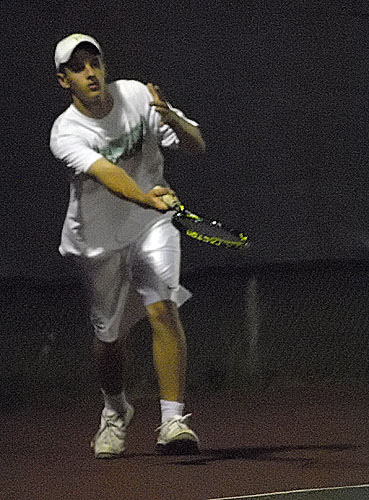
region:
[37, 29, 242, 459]
tennis player wearing all white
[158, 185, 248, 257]
black and yellow tennis racket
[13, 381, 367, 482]
brown part of tennis court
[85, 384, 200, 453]
white shoes and socks of tennis player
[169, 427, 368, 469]
shadow of player on court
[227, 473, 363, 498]
white line on tennis court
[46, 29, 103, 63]
white hat of tennis player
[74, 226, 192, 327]
white shorts with black Nike swoosh of tennis player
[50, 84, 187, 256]
white shirt of tennis player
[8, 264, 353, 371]
fencing behind tennis player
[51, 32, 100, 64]
A white cap in the photo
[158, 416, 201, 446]
White sport shoe in the photo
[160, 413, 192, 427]
Shoe lace in the photo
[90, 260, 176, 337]
White shorts in the photo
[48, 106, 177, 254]
White t-shirt in the photo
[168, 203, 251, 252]
A tennis racket in the photo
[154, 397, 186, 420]
White socks in the photo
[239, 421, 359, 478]
A tennis pitch in the photo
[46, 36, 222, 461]
A tennis player in the photo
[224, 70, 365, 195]
A dark wall in the photo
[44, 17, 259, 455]
man playing tennis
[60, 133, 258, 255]
man holding tennis racket out to hit ball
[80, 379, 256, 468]
white tennis sneakers and socks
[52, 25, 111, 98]
man wearing a white baseball hat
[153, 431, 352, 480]
man's shadow on the tennis court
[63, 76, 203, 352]
white tennis shorts and a t-shirt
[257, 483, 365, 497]
white line on tennis court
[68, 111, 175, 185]
green deisgn on white t-shirt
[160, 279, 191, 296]
black nike swish on white shors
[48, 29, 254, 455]
Man playing tennis on court.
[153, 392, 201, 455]
White sock on ankle.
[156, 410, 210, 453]
White shoelace in shoes.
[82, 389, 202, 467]
White shoes on feet.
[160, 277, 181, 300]
Nike symbol on bottom of shorts.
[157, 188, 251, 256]
Black and green tennis racquet.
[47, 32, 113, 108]
White cap on man's head.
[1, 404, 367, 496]
Red colored court floor.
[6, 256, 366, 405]
Black fence in the background.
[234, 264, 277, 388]
Gray pole behind the fence.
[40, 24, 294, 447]
a male tennis player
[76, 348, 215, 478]
the tennis shoes are white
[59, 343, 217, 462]
the socks are white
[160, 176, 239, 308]
the racket is black and green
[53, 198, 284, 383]
tennis player wears shorts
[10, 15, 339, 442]
the photo is grainy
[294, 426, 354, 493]
the lines on the court are white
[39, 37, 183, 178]
his baseball hat is white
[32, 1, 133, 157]
the hat is a baseball hat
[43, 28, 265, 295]
he is waiting to return the ball